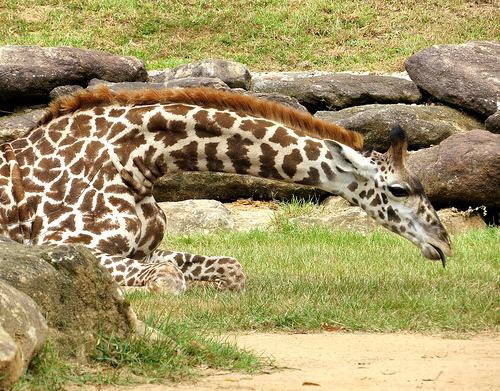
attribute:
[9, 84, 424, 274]
giraffe — reclined, white, brown, sitting, kneeling, large, resting, leaning, big, seated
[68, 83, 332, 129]
mane — brown, long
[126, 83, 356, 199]
neck — giraffe's, long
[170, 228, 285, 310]
knees — folded, giraffe's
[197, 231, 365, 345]
grass — short, green, patch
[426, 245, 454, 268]
tongue — sticking out, out, giraffe's, longue, grey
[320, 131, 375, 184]
ear — white, giraffe's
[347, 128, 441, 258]
head — giraffe's, graffe's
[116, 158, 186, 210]
bottom of neck — wrinkled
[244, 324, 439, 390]
dirt — brown, sand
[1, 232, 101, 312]
rocks — large, several, grey, big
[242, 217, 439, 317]
patches — grass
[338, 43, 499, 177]
boulder rocks — large, grey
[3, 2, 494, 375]
outdoor — sunny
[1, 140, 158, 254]
body — giraffe's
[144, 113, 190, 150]
spots — brown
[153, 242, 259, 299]
legs — bent, giraffe's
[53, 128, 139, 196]
fur — brown